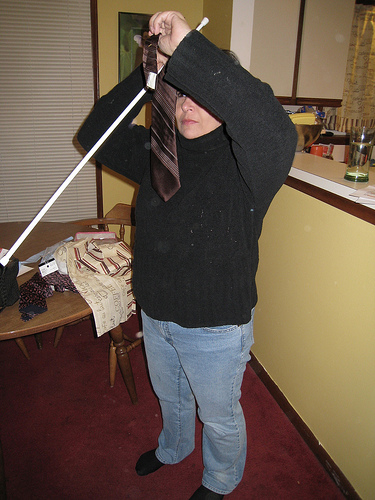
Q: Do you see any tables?
A: Yes, there is a table.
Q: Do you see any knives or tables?
A: Yes, there is a table.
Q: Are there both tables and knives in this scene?
A: No, there is a table but no knives.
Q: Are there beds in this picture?
A: No, there are no beds.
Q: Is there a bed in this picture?
A: No, there are no beds.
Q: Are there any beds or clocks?
A: No, there are no beds or clocks.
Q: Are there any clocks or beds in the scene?
A: No, there are no beds or clocks.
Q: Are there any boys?
A: No, there are no boys.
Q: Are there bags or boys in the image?
A: No, there are no boys or bags.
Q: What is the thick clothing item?
A: The clothing item is a sweater.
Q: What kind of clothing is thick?
A: The clothing is a sweater.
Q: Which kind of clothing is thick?
A: The clothing is a sweater.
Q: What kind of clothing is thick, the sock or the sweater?
A: The sweater is thick.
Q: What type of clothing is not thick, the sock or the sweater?
A: The sock is not thick.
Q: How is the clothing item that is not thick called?
A: The clothing item is a sock.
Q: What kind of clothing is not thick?
A: The clothing is a sock.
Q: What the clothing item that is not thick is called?
A: The clothing item is a sock.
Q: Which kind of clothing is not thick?
A: The clothing is a sock.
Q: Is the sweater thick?
A: Yes, the sweater is thick.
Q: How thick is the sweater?
A: The sweater is thick.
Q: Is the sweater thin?
A: No, the sweater is thick.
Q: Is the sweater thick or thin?
A: The sweater is thick.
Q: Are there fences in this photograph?
A: No, there are no fences.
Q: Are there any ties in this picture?
A: Yes, there is a tie.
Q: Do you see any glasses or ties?
A: Yes, there is a tie.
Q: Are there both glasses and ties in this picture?
A: Yes, there are both a tie and glasses.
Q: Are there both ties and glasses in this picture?
A: Yes, there are both a tie and glasses.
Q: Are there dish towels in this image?
A: No, there are no dish towels.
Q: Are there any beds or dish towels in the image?
A: No, there are no dish towels or beds.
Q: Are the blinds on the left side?
A: Yes, the blinds are on the left of the image.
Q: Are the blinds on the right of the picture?
A: No, the blinds are on the left of the image.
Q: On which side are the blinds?
A: The blinds are on the left of the image.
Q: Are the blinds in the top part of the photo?
A: Yes, the blinds are in the top of the image.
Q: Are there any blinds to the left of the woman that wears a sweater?
A: Yes, there are blinds to the left of the woman.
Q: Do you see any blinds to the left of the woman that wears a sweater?
A: Yes, there are blinds to the left of the woman.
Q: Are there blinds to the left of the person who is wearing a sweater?
A: Yes, there are blinds to the left of the woman.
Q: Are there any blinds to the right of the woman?
A: No, the blinds are to the left of the woman.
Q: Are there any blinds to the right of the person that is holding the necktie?
A: No, the blinds are to the left of the woman.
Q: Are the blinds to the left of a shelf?
A: No, the blinds are to the left of a woman.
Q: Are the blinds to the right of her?
A: No, the blinds are to the left of the woman.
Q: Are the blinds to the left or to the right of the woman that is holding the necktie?
A: The blinds are to the left of the woman.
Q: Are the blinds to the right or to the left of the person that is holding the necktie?
A: The blinds are to the left of the woman.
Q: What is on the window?
A: The blinds are on the window.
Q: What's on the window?
A: The blinds are on the window.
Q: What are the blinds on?
A: The blinds are on the window.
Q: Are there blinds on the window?
A: Yes, there are blinds on the window.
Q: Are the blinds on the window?
A: Yes, the blinds are on the window.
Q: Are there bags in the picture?
A: No, there are no bags.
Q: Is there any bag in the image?
A: No, there are no bags.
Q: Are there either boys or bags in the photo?
A: No, there are no bags or boys.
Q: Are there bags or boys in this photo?
A: No, there are no bags or boys.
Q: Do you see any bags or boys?
A: No, there are no bags or boys.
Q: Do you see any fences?
A: No, there are no fences.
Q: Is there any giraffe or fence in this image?
A: No, there are no fences or giraffes.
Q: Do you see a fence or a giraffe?
A: No, there are no fences or giraffes.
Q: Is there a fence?
A: No, there are no fences.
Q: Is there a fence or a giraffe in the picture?
A: No, there are no fences or giraffes.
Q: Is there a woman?
A: Yes, there is a woman.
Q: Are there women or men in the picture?
A: Yes, there is a woman.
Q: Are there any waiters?
A: No, there are no waiters.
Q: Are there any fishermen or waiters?
A: No, there are no waiters or fishermen.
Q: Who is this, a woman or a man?
A: This is a woman.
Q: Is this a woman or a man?
A: This is a woman.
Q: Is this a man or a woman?
A: This is a woman.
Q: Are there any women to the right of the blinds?
A: Yes, there is a woman to the right of the blinds.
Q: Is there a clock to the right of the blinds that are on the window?
A: No, there is a woman to the right of the blinds.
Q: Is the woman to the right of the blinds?
A: Yes, the woman is to the right of the blinds.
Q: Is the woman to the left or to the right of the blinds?
A: The woman is to the right of the blinds.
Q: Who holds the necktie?
A: The woman holds the necktie.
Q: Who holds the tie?
A: The woman holds the necktie.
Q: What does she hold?
A: The woman holds the tie.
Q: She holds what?
A: The woman holds the tie.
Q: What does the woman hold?
A: The woman holds the tie.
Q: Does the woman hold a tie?
A: Yes, the woman holds a tie.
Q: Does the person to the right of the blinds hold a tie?
A: Yes, the woman holds a tie.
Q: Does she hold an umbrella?
A: No, the woman holds a tie.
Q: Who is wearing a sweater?
A: The woman is wearing a sweater.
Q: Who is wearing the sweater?
A: The woman is wearing a sweater.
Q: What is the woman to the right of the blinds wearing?
A: The woman is wearing a sweater.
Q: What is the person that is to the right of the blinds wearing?
A: The woman is wearing a sweater.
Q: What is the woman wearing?
A: The woman is wearing a sweater.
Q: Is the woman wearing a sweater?
A: Yes, the woman is wearing a sweater.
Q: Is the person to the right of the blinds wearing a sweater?
A: Yes, the woman is wearing a sweater.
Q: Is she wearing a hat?
A: No, the woman is wearing a sweater.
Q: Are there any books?
A: No, there are no books.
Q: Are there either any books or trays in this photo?
A: No, there are no books or trays.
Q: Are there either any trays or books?
A: No, there are no books or trays.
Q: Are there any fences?
A: No, there are no fences.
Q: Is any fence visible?
A: No, there are no fences.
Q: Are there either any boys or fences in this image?
A: No, there are no fences or boys.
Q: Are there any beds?
A: No, there are no beds.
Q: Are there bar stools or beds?
A: No, there are no beds or bar stools.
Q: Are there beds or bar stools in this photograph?
A: No, there are no beds or bar stools.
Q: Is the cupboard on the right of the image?
A: Yes, the cupboard is on the right of the image.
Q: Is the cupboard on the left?
A: No, the cupboard is on the right of the image.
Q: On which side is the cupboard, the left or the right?
A: The cupboard is on the right of the image.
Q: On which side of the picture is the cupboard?
A: The cupboard is on the right of the image.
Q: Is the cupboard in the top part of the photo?
A: Yes, the cupboard is in the top of the image.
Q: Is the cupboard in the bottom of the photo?
A: No, the cupboard is in the top of the image.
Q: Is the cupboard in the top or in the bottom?
A: The cupboard is in the top of the image.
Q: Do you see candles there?
A: No, there are no candles.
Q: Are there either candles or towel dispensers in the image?
A: No, there are no candles or towel dispensers.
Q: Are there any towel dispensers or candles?
A: No, there are no candles or towel dispensers.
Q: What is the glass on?
A: The glass is on the counter.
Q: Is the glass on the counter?
A: Yes, the glass is on the counter.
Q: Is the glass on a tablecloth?
A: No, the glass is on the counter.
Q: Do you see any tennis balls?
A: No, there are no tennis balls.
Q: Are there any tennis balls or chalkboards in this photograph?
A: No, there are no tennis balls or chalkboards.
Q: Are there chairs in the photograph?
A: Yes, there is a chair.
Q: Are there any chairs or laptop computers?
A: Yes, there is a chair.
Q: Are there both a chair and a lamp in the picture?
A: No, there is a chair but no lamps.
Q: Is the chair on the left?
A: Yes, the chair is on the left of the image.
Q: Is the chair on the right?
A: No, the chair is on the left of the image.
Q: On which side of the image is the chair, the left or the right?
A: The chair is on the left of the image.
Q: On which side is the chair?
A: The chair is on the left of the image.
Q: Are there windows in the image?
A: Yes, there is a window.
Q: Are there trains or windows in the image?
A: Yes, there is a window.